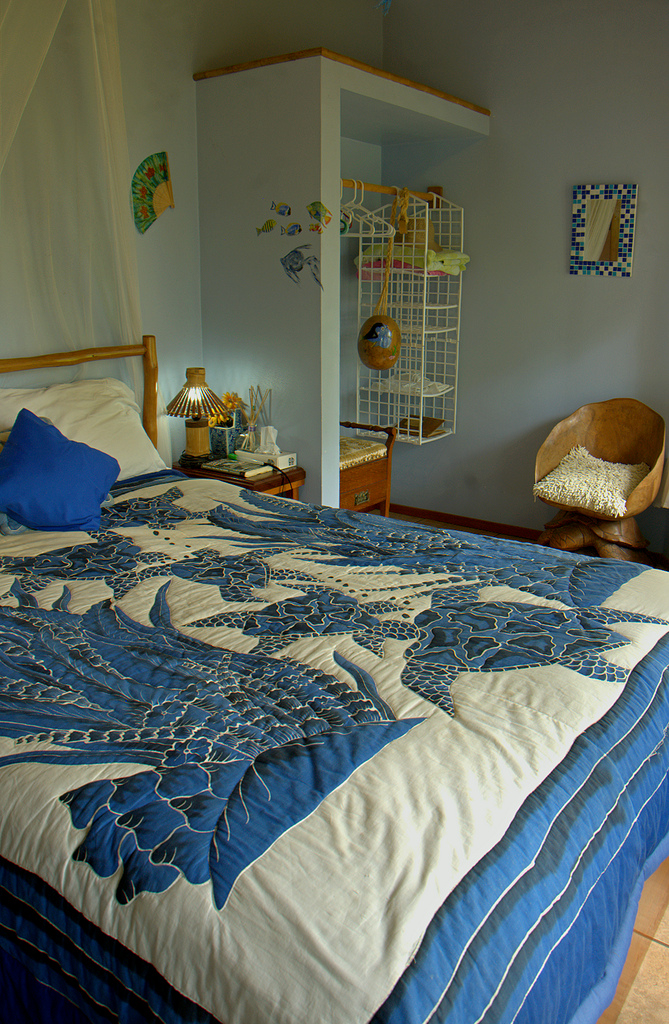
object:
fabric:
[79, 802, 151, 867]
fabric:
[124, 799, 189, 846]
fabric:
[193, 751, 250, 806]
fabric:
[322, 638, 414, 728]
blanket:
[0, 458, 668, 1019]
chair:
[530, 392, 666, 557]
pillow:
[536, 438, 662, 517]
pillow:
[0, 403, 124, 531]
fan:
[127, 153, 175, 234]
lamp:
[167, 358, 231, 475]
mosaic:
[621, 202, 629, 272]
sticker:
[274, 240, 332, 295]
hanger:
[338, 178, 377, 240]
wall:
[390, 65, 647, 516]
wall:
[2, 2, 236, 448]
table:
[176, 444, 304, 498]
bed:
[3, 329, 669, 1019]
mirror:
[564, 181, 637, 278]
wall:
[142, 2, 530, 508]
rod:
[328, 168, 441, 208]